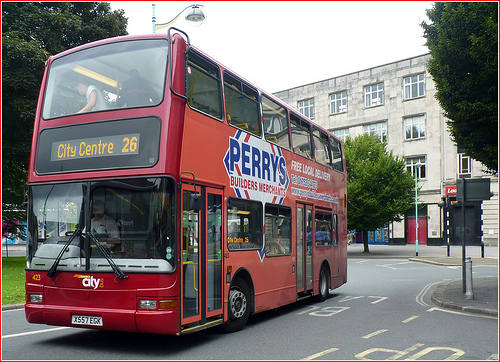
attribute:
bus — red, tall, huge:
[40, 54, 350, 324]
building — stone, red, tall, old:
[341, 61, 429, 136]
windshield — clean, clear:
[29, 190, 180, 258]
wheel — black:
[225, 288, 258, 324]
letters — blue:
[229, 137, 287, 185]